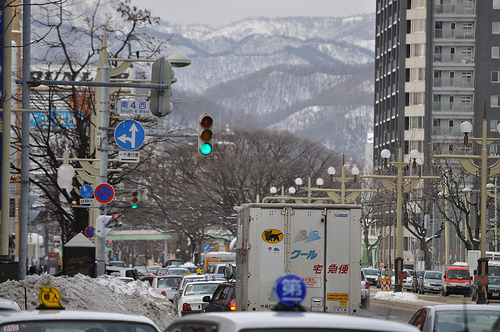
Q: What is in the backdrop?
A: Mountains.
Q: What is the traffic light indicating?
A: Green signal.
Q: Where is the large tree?
A: In the distance.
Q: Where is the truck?
A: On the road.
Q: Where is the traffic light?
A: Above the street.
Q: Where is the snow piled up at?
A: On the side of the road.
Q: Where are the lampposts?
A: On the side of the street.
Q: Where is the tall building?
A: On the side of the street.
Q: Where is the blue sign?
A: Next to the traffic light.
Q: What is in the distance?
A: The large mountains.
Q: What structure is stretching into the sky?
A: The tall building.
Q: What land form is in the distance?
A: A mountain range.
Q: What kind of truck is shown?
A: A white commercial truck.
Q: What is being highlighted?
A: An overhead street light.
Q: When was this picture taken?
A: Daytime.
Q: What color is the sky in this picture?
A: Grey.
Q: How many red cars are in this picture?
A: One.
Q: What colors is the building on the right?
A: Black and White.